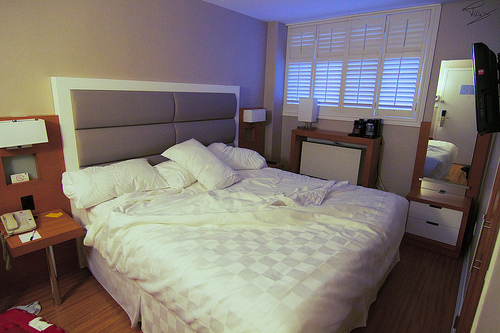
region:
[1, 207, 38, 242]
land line telephone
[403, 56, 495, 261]
mirrored nightstand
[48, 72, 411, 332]
unmade bed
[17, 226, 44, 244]
pen and a small piece of notepaper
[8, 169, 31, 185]
information card from the management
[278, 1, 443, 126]
white shuttered window with louvers drawn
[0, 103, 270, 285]
two square wall mounted lights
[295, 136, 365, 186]
room heater/cooling unit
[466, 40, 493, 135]
wall mounted television set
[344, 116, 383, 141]
coffee maker and supplies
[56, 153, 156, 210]
white pillow on a bed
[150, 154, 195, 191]
white pillow on a bed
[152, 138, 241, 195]
white pillow on a bed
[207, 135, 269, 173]
white pillow on a bed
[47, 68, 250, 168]
headboard of a bed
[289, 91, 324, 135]
table lamp with white shade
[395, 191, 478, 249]
dresser with white drawers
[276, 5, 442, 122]
window with white shutters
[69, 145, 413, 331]
white comforter on bed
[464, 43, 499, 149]
black tv mounted on wall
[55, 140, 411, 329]
A large unmade bed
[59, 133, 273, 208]
White pillows on the bed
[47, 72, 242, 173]
A grey and white headrest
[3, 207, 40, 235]
A landline telephone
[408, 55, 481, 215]
A mirror reflecting the room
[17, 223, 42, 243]
A piece of paper with a pen on it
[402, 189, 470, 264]
A chest of drawers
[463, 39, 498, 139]
A television mounted on the wall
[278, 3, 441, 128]
The slatted window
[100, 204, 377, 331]
Grey and white checkered bedsheets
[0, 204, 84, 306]
a wooden table on a silver metal pole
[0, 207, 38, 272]
a corded tan colored telephone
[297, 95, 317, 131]
a lamp with a white shade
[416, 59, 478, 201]
a mirror hanging on the wall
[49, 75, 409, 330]
a bed with white bed covering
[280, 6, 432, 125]
a window with white blinds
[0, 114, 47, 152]
a light with a white shade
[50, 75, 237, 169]
a white and gray headboard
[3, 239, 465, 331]
a brown hardwood floor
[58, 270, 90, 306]
shadow on the hardwood floor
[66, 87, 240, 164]
Grey padding attached to head board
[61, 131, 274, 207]
Four white pillows on bed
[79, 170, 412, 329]
White checkered bed cover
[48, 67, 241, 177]
White and grey headboard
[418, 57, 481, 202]
Small mirror over white and brown shelf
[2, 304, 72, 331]
Red and white object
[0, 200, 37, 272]
Old school brown land telephone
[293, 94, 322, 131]
White lamp on top of brown and white desk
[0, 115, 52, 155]
White wall mounted lamp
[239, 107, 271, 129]
White wall mounted lamp